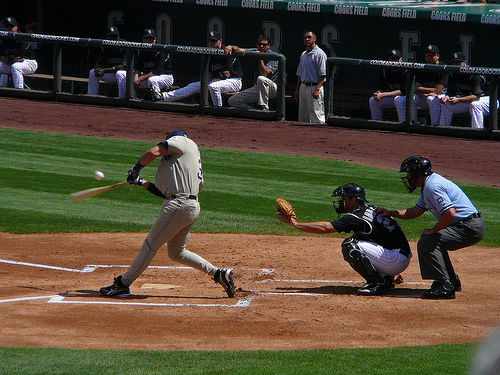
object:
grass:
[0, 128, 498, 375]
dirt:
[0, 99, 498, 192]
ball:
[90, 168, 104, 181]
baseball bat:
[65, 180, 155, 200]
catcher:
[272, 181, 412, 296]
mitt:
[272, 197, 297, 224]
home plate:
[140, 281, 185, 291]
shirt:
[413, 171, 475, 223]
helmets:
[420, 47, 444, 57]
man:
[294, 28, 327, 122]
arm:
[294, 216, 360, 234]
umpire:
[373, 154, 482, 302]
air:
[0, 0, 498, 374]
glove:
[122, 167, 137, 184]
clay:
[0, 99, 499, 351]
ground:
[0, 88, 499, 374]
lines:
[0, 260, 274, 276]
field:
[0, 97, 499, 374]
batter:
[100, 128, 235, 301]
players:
[224, 35, 280, 111]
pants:
[296, 85, 326, 129]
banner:
[173, 0, 499, 26]